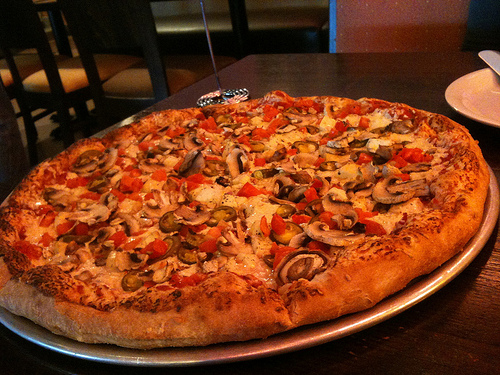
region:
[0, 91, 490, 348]
a large deep dish pizza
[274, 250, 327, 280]
a mushroom slice on the pizza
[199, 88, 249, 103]
the coiled base of a sign holder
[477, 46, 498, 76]
the handle of a piece of silverware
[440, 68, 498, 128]
half of a white porcelain plate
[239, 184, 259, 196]
a piece of red bell pepper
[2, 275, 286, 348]
the crust of a slice of pizza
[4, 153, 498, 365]
the metal rim of a pizza tray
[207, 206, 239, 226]
a slice of jalapeno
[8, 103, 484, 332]
the pizza has many toppings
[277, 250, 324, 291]
a mushroom on the pizza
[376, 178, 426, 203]
a mushroom on the pizza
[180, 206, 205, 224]
a mushroom on the pizza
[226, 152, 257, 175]
a mushroom on the pizza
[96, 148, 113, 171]
a mushroom on the pizza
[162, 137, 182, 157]
a mushroom on the pizza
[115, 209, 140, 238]
a mushroom on the pizza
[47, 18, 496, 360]
a pizza on a table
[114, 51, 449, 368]
a pizza on pan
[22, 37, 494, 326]
a baked pizza on a table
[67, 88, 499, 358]
a baked pizza on a pan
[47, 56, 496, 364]
a cooked pizza on a table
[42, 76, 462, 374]
a cooked pizza on table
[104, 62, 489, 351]
a large baked pizza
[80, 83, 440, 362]
a large cooked pizza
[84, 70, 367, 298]
a pizza with toppings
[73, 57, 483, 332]
toppings on a pizza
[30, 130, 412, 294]
pizza on silver tray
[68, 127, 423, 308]
pizza has brown crust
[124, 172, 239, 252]
green peppers on pizza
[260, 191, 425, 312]
grey mushrooms on pizza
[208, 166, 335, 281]
red tomatoes on pizza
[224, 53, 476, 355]
tray on brown table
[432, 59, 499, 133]
white plate on table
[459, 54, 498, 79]
spatula on white plate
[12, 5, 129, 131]
brown cushion on chair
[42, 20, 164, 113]
chair is dark brown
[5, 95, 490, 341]
Round pizza on pan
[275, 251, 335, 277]
Cooked mushroom on pizza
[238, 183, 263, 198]
Tomato on top of pizza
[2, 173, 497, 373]
Silver tray under pizza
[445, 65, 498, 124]
White plate near pizza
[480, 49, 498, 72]
Silver utensil on plate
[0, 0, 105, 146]
Wooden chairs on floor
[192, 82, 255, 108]
Base of sign holder near pizza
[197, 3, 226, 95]
Thin pole of sign holder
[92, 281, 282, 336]
Burned crust on pizza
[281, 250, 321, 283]
mushroom on the pizza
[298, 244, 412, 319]
crust of a pizza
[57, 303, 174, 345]
crust of a pizza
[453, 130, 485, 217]
crust of a pizza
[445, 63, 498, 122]
the plate is white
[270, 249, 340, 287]
brown mushroom on pizza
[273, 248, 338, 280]
brown mushroom on pizza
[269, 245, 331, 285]
brown mushroom on pizza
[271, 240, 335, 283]
brown mushroom on pizza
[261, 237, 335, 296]
brown mushroom on pizza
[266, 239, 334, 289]
brown mushroom on pizza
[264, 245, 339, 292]
brown mushroom on pizza